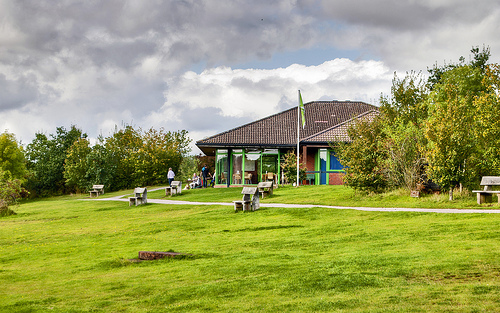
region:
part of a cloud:
[226, 13, 254, 46]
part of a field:
[293, 243, 335, 308]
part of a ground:
[239, 210, 264, 257]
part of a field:
[256, 225, 294, 292]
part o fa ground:
[258, 233, 295, 298]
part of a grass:
[316, 209, 341, 254]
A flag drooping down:
[298, 88, 305, 128]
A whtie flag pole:
[296, 121, 299, 178]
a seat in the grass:
[130, 188, 147, 205]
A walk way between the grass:
[371, 207, 406, 210]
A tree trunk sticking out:
[139, 250, 169, 260]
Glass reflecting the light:
[320, 148, 327, 156]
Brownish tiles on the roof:
[257, 124, 292, 138]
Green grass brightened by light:
[242, 252, 345, 272]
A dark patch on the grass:
[437, 275, 472, 282]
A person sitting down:
[185, 171, 200, 188]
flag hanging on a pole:
[296, 89, 308, 185]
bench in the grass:
[466, 171, 499, 200]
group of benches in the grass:
[82, 174, 282, 218]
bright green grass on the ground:
[5, 181, 492, 311]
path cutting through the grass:
[126, 188, 499, 225]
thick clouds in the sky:
[1, 0, 499, 156]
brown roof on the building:
[202, 92, 392, 149]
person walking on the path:
[165, 163, 176, 186]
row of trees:
[1, 126, 191, 200]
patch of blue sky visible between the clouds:
[239, 48, 353, 71]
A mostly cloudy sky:
[1, 1, 499, 157]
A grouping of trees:
[1, 121, 198, 203]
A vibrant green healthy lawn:
[0, 182, 499, 312]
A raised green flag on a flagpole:
[294, 87, 306, 189]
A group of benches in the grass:
[86, 174, 498, 213]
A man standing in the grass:
[165, 165, 176, 188]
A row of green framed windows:
[213, 147, 283, 188]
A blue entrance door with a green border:
[313, 145, 330, 187]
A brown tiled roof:
[193, 97, 389, 147]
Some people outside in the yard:
[183, 164, 214, 191]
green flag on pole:
[296, 89, 309, 183]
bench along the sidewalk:
[234, 173, 259, 220]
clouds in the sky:
[85, 20, 388, 90]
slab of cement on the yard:
[139, 240, 188, 270]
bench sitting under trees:
[380, 55, 498, 231]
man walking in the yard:
[159, 162, 177, 184]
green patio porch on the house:
[213, 147, 283, 188]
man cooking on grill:
[200, 165, 217, 187]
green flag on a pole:
[296, 88, 316, 133]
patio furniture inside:
[235, 168, 253, 186]